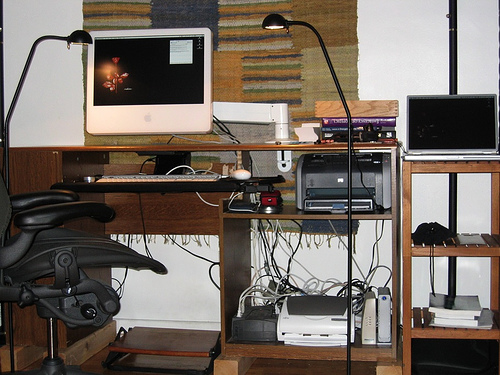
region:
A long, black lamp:
[262, 14, 352, 374]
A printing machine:
[275, 294, 354, 346]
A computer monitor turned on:
[88, 28, 212, 133]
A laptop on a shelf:
[405, 93, 498, 158]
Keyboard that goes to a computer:
[100, 174, 224, 181]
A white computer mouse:
[230, 169, 250, 179]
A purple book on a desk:
[322, 117, 397, 124]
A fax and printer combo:
[295, 151, 391, 212]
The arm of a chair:
[14, 200, 116, 227]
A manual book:
[427, 290, 479, 314]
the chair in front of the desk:
[0, 176, 165, 374]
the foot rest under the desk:
[100, 327, 220, 372]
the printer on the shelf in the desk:
[295, 153, 390, 215]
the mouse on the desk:
[230, 168, 250, 180]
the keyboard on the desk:
[96, 174, 222, 183]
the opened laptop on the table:
[404, 94, 499, 160]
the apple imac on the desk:
[85, 27, 212, 132]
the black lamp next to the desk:
[262, 12, 352, 374]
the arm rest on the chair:
[14, 200, 116, 230]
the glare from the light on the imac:
[95, 59, 127, 92]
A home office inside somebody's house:
[5, 15, 495, 356]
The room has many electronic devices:
[2, 20, 490, 371]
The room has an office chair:
[7, 28, 493, 371]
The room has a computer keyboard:
[8, 12, 493, 364]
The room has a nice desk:
[5, 17, 496, 368]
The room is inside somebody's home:
[6, 10, 496, 370]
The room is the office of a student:
[2, 20, 495, 371]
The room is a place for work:
[10, 21, 490, 364]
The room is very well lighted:
[9, 19, 496, 373]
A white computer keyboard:
[95, 168, 223, 188]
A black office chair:
[0, 159, 173, 372]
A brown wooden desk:
[8, 139, 404, 373]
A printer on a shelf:
[290, 144, 398, 224]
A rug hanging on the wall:
[77, 1, 366, 253]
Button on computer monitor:
[136, 108, 156, 127]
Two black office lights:
[3, 10, 358, 146]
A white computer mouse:
[224, 160, 258, 185]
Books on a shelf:
[423, 290, 495, 334]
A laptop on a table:
[400, 89, 499, 172]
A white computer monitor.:
[85, 23, 210, 131]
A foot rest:
[105, 320, 220, 366]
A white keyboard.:
[95, 170, 220, 180]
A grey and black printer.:
[292, 152, 384, 209]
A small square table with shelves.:
[397, 150, 493, 370]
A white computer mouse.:
[230, 162, 251, 178]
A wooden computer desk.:
[4, 139, 400, 374]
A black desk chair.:
[1, 141, 170, 373]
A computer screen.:
[405, 93, 499, 155]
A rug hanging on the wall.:
[80, 0, 363, 250]